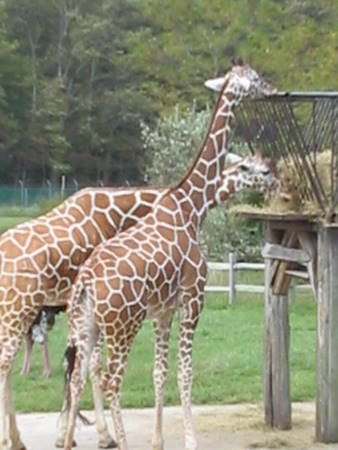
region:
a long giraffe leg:
[174, 300, 202, 448]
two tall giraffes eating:
[1, 67, 272, 443]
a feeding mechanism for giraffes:
[226, 85, 337, 213]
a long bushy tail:
[51, 278, 90, 383]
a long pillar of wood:
[252, 217, 291, 432]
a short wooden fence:
[202, 257, 332, 306]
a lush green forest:
[3, 2, 337, 175]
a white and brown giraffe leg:
[173, 309, 210, 448]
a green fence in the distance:
[2, 186, 61, 214]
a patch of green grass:
[8, 287, 328, 401]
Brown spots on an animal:
[94, 290, 123, 314]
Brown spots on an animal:
[113, 273, 169, 323]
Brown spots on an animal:
[82, 237, 135, 278]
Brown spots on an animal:
[121, 224, 160, 269]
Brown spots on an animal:
[150, 193, 187, 241]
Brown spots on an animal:
[180, 238, 215, 322]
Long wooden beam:
[238, 230, 321, 444]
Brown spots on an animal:
[79, 181, 118, 218]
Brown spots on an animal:
[37, 204, 102, 246]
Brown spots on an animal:
[9, 218, 31, 263]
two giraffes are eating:
[31, 54, 318, 378]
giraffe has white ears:
[201, 35, 275, 123]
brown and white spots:
[70, 91, 258, 339]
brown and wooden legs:
[253, 216, 335, 439]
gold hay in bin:
[258, 136, 334, 226]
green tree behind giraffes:
[133, 94, 256, 312]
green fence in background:
[7, 180, 69, 210]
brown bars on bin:
[234, 96, 311, 216]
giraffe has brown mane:
[145, 79, 229, 231]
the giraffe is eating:
[191, 119, 291, 231]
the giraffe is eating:
[215, 142, 290, 200]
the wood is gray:
[256, 229, 299, 438]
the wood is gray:
[306, 221, 335, 447]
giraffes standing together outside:
[12, 42, 328, 380]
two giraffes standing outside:
[46, 64, 319, 432]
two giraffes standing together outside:
[24, 160, 306, 446]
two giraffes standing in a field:
[14, 166, 255, 448]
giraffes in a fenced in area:
[24, 146, 328, 426]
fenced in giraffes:
[28, 164, 306, 431]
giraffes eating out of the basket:
[44, 74, 336, 372]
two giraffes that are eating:
[32, 29, 337, 396]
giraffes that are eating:
[38, 139, 325, 442]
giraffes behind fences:
[28, 126, 318, 442]